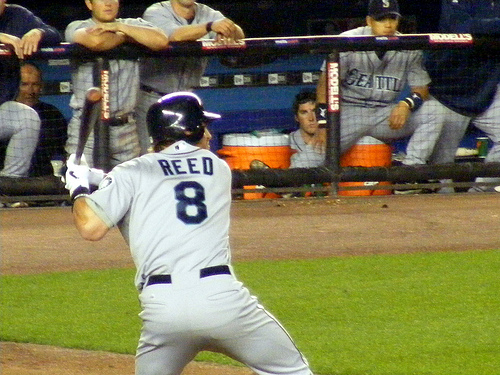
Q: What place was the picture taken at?
A: It was taken at the field.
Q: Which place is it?
A: It is a field.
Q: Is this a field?
A: Yes, it is a field.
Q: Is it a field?
A: Yes, it is a field.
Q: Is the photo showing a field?
A: Yes, it is showing a field.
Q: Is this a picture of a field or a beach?
A: It is showing a field.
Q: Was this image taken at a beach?
A: No, the picture was taken in a field.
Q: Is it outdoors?
A: Yes, it is outdoors.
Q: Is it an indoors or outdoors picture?
A: It is outdoors.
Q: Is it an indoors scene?
A: No, it is outdoors.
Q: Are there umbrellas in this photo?
A: No, there are no umbrellas.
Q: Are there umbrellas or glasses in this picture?
A: No, there are no umbrellas or glasses.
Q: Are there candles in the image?
A: No, there are no candles.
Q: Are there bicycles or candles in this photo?
A: No, there are no candles or bicycles.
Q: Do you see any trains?
A: No, there are no trains.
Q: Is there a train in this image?
A: No, there are no trains.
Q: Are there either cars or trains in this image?
A: No, there are no trains or cars.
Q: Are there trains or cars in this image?
A: No, there are no trains or cars.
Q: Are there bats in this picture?
A: Yes, there is a bat.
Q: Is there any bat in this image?
A: Yes, there is a bat.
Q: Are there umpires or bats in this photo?
A: Yes, there is a bat.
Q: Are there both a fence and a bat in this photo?
A: Yes, there are both a bat and a fence.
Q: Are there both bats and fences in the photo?
A: Yes, there are both a bat and a fence.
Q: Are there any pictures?
A: No, there are no pictures.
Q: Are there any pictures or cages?
A: No, there are no pictures or cages.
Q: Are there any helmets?
A: Yes, there is a helmet.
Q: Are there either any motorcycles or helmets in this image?
A: Yes, there is a helmet.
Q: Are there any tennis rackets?
A: No, there are no tennis rackets.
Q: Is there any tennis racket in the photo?
A: No, there are no rackets.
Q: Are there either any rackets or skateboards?
A: No, there are no rackets or skateboards.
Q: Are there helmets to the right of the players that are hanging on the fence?
A: Yes, there is a helmet to the right of the players.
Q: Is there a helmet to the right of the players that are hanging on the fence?
A: Yes, there is a helmet to the right of the players.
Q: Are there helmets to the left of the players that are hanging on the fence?
A: No, the helmet is to the right of the players.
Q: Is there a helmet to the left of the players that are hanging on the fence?
A: No, the helmet is to the right of the players.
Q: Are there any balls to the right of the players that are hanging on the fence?
A: No, there is a helmet to the right of the players.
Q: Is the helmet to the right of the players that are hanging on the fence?
A: Yes, the helmet is to the right of the players.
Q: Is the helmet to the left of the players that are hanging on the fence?
A: No, the helmet is to the right of the players.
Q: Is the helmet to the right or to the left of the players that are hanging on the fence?
A: The helmet is to the right of the players.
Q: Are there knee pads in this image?
A: No, there are no knee pads.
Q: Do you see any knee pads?
A: No, there are no knee pads.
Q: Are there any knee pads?
A: No, there are no knee pads.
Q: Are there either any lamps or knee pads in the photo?
A: No, there are no knee pads or lamps.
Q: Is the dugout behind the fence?
A: Yes, the dugout is behind the fence.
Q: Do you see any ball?
A: No, there are no balls.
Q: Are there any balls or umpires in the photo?
A: No, there are no balls or umpires.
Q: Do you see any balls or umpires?
A: No, there are no balls or umpires.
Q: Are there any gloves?
A: Yes, there are gloves.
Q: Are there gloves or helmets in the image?
A: Yes, there are gloves.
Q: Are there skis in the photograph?
A: No, there are no skis.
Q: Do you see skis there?
A: No, there are no skis.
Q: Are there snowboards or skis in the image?
A: No, there are no skis or snowboards.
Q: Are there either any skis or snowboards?
A: No, there are no skis or snowboards.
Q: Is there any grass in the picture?
A: Yes, there is grass.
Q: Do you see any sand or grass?
A: Yes, there is grass.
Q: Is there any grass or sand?
A: Yes, there is grass.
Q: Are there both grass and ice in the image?
A: No, there is grass but no ice.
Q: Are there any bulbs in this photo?
A: No, there are no bulbs.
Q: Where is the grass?
A: The grass is on the field.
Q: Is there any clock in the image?
A: No, there are no clocks.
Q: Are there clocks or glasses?
A: No, there are no clocks or glasses.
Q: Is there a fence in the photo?
A: Yes, there is a fence.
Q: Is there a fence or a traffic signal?
A: Yes, there is a fence.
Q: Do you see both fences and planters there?
A: No, there is a fence but no planters.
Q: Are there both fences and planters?
A: No, there is a fence but no planters.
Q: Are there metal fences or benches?
A: Yes, there is a metal fence.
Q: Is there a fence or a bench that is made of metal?
A: Yes, the fence is made of metal.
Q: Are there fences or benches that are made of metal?
A: Yes, the fence is made of metal.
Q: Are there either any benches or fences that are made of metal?
A: Yes, the fence is made of metal.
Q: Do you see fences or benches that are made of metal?
A: Yes, the fence is made of metal.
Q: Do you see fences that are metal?
A: Yes, there is a metal fence.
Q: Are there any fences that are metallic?
A: Yes, there is a fence that is metallic.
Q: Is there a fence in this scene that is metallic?
A: Yes, there is a fence that is metallic.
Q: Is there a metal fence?
A: Yes, there is a fence that is made of metal.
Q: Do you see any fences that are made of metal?
A: Yes, there is a fence that is made of metal.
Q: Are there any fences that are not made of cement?
A: Yes, there is a fence that is made of metal.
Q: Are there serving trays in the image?
A: No, there are no serving trays.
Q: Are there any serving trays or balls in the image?
A: No, there are no serving trays or balls.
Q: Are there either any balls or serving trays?
A: No, there are no serving trays or balls.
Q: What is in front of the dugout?
A: The fence is in front of the dugout.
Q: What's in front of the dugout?
A: The fence is in front of the dugout.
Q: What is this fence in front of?
A: The fence is in front of the dugout.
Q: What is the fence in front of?
A: The fence is in front of the dugout.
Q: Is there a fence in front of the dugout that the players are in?
A: Yes, there is a fence in front of the dugout.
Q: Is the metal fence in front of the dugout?
A: Yes, the fence is in front of the dugout.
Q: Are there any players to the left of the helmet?
A: Yes, there are players to the left of the helmet.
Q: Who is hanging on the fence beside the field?
A: The players are hanging on the fence.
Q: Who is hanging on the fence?
A: The players are hanging on the fence.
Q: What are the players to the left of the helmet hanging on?
A: The players are hanging on the fence.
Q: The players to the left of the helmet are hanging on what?
A: The players are hanging on the fence.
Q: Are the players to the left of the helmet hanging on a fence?
A: Yes, the players are hanging on a fence.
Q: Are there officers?
A: No, there are no officers.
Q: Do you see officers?
A: No, there are no officers.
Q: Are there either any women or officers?
A: No, there are no officers or women.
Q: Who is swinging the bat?
A: The player is swinging the bat.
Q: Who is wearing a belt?
A: The player is wearing a belt.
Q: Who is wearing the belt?
A: The player is wearing a belt.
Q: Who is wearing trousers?
A: The player is wearing trousers.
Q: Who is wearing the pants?
A: The player is wearing trousers.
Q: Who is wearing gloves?
A: The player is wearing gloves.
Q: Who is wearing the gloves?
A: The player is wearing gloves.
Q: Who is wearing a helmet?
A: The player is wearing a helmet.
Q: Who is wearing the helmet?
A: The player is wearing a helmet.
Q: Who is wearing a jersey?
A: The player is wearing a jersey.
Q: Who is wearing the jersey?
A: The player is wearing a jersey.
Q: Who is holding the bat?
A: The player is holding the bat.